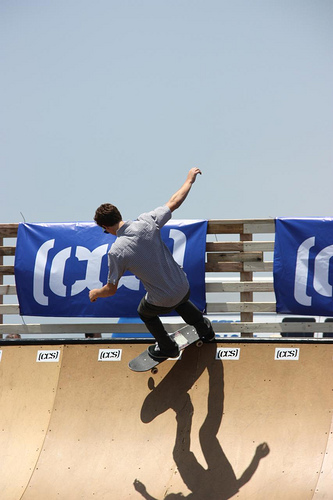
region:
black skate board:
[132, 329, 202, 373]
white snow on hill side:
[90, 136, 111, 166]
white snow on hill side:
[230, 148, 253, 172]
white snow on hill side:
[149, 72, 165, 87]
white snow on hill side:
[13, 96, 43, 133]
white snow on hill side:
[256, 7, 277, 45]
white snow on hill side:
[120, 63, 146, 113]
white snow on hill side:
[66, 109, 88, 136]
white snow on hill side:
[58, 79, 107, 120]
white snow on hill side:
[118, 57, 197, 138]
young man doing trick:
[58, 174, 210, 419]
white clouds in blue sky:
[20, 46, 45, 79]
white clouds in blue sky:
[265, 166, 282, 189]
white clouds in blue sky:
[235, 63, 266, 106]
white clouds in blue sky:
[123, 54, 142, 80]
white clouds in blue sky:
[34, 121, 73, 191]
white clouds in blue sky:
[83, 43, 124, 104]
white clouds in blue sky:
[51, 63, 73, 101]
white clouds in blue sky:
[116, 92, 143, 144]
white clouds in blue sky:
[27, 96, 55, 127]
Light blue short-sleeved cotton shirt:
[97, 208, 194, 307]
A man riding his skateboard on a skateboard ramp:
[82, 168, 227, 375]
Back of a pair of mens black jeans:
[133, 291, 210, 349]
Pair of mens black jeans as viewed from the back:
[141, 288, 209, 345]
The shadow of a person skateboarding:
[130, 362, 268, 498]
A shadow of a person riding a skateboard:
[141, 368, 275, 498]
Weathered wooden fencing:
[212, 219, 275, 332]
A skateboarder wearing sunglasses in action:
[80, 165, 224, 379]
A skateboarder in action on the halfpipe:
[81, 165, 233, 378]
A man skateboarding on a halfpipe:
[80, 165, 242, 373]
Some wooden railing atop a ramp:
[0, 215, 331, 334]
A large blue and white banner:
[11, 217, 206, 312]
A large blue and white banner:
[268, 213, 325, 311]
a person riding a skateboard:
[85, 163, 212, 353]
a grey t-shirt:
[103, 201, 187, 303]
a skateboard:
[125, 312, 209, 374]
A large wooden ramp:
[1, 337, 331, 499]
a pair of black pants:
[135, 278, 206, 349]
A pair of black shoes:
[145, 317, 216, 360]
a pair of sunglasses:
[101, 226, 109, 234]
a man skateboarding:
[86, 148, 236, 374]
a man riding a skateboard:
[78, 189, 275, 438]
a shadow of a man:
[64, 256, 276, 498]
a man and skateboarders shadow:
[73, 238, 326, 497]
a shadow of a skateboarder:
[63, 199, 331, 462]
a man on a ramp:
[65, 211, 285, 475]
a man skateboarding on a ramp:
[79, 193, 297, 447]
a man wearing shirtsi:
[95, 205, 231, 352]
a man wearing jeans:
[74, 209, 297, 438]